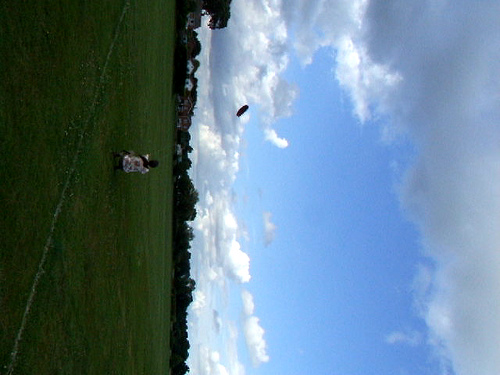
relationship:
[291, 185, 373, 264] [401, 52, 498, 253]
blue sky with clouds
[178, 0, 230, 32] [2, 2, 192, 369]
tree lining field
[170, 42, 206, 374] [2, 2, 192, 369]
foliage lining field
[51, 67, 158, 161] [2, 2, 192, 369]
line drawn on field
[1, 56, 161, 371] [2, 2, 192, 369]
grass in field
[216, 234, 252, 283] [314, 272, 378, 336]
cloud in sky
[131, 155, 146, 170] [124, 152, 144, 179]
blemish on back of shirt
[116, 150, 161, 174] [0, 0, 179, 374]
person in grass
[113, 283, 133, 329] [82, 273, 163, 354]
pale patch in grass